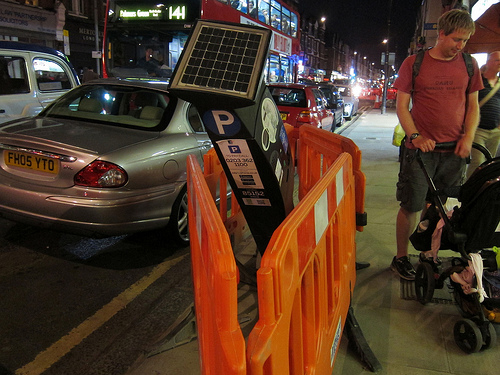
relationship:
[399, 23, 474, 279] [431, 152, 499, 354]
man holds stroller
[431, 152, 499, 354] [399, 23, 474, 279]
stroller in front of man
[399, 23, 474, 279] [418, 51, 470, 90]
man has backpack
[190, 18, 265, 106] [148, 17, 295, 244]
solar panel on meter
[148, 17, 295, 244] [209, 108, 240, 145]
meter has p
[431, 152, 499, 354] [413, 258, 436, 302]
stroller has wheel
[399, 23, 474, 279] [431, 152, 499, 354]
man pushes stroller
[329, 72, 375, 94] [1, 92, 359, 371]
lights near street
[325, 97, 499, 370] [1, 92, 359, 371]
sidewalk near street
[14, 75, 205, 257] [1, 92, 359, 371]
car in street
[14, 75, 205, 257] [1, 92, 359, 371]
car on street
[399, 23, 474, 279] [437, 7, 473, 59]
man has head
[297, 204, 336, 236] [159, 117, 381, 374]
square on barricades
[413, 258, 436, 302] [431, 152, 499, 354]
wheel on stroller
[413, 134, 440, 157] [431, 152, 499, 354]
hand on stroller